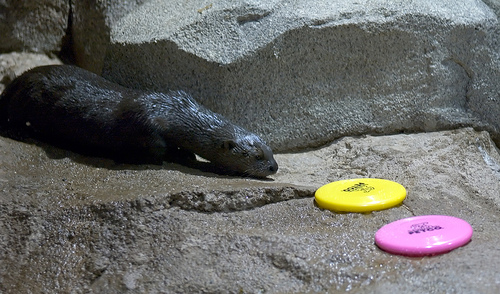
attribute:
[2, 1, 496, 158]
rock — gray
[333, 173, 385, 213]
frisbee — yellow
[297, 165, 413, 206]
frisbee — yellow, plastic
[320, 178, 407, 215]
frisbee — yellow, pink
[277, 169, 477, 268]
frisbee — bright, yellow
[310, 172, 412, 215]
frisbee — yellow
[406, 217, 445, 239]
writing — purple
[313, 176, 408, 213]
frisbee — yellow, round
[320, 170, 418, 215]
frisbee — yellow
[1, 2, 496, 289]
boulder — large, grey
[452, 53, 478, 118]
crack — large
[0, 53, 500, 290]
rock — large, wet, brown, gray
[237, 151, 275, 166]
eye — small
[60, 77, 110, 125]
fur — dark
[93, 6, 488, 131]
boulder — large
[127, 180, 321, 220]
crack — large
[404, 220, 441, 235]
writing — purple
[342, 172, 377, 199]
frisbee — yellow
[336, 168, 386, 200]
writing — black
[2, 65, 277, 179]
otter — brown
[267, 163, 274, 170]
nostril — black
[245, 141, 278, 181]
face — otter's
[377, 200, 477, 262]
frisbee — pink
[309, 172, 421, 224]
frisbee — yellow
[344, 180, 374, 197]
writing — dark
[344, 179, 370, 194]
writing — dark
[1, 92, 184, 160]
fur — wet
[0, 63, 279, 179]
animal — black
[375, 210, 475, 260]
frisbee — pink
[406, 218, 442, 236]
lettering — purple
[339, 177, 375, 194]
writing — black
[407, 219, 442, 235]
writing — black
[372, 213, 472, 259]
frisbee — pink, round